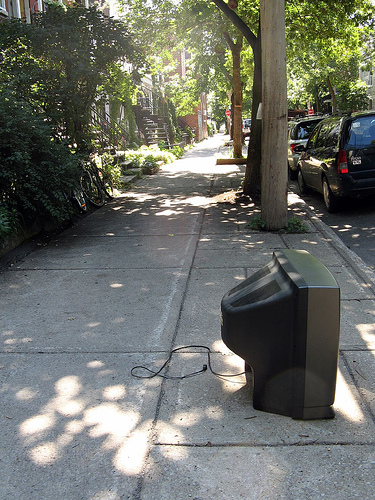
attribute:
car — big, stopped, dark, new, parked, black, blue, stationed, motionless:
[297, 112, 374, 208]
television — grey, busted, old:
[222, 249, 343, 422]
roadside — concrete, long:
[160, 152, 216, 500]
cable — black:
[128, 343, 214, 383]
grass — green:
[285, 221, 304, 232]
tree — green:
[20, 6, 147, 150]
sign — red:
[308, 109, 314, 115]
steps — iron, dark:
[126, 109, 173, 142]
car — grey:
[286, 118, 312, 146]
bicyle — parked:
[79, 146, 121, 204]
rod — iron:
[91, 108, 129, 171]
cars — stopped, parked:
[286, 111, 375, 209]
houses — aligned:
[118, 26, 205, 130]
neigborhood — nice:
[3, 4, 375, 245]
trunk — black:
[343, 150, 375, 168]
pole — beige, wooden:
[261, 1, 286, 230]